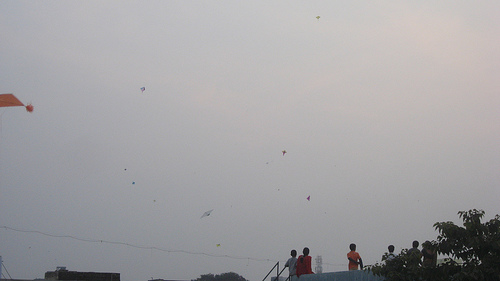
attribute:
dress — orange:
[296, 247, 313, 272]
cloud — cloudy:
[210, 53, 335, 107]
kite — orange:
[0, 92, 33, 112]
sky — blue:
[0, 1, 500, 279]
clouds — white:
[344, 65, 481, 153]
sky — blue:
[39, 19, 96, 257]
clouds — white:
[278, 40, 480, 222]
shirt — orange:
[345, 250, 362, 270]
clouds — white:
[60, 15, 128, 73]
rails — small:
[258, 257, 309, 279]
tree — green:
[362, 208, 498, 279]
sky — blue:
[50, 22, 475, 205]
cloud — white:
[359, 13, 497, 120]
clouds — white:
[219, 15, 493, 169]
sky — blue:
[173, 50, 496, 200]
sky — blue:
[93, 17, 485, 237]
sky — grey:
[75, 24, 482, 198]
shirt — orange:
[348, 251, 368, 274]